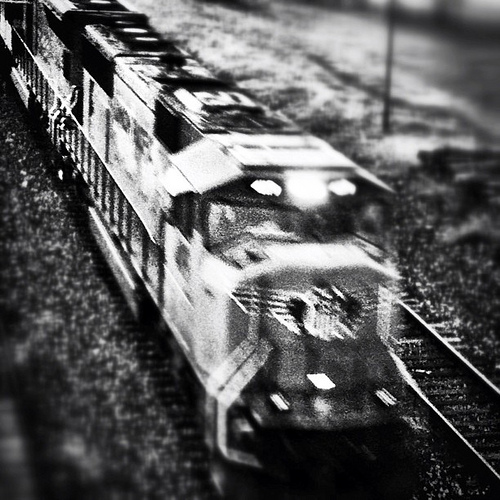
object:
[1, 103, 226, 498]
gravel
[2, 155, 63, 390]
train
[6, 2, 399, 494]
train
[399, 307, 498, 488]
tracks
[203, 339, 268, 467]
bar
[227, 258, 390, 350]
engine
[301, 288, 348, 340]
logo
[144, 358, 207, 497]
tracks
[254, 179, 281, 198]
lights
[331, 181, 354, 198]
lights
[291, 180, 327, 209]
light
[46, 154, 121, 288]
rail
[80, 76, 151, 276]
side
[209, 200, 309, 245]
window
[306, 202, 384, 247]
window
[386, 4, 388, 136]
post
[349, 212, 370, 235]
engineer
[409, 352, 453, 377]
wood planks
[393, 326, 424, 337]
wood planks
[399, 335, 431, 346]
wood planks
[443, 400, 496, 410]
wood planks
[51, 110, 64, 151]
metal bars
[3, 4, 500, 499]
picture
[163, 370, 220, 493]
track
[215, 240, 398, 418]
front